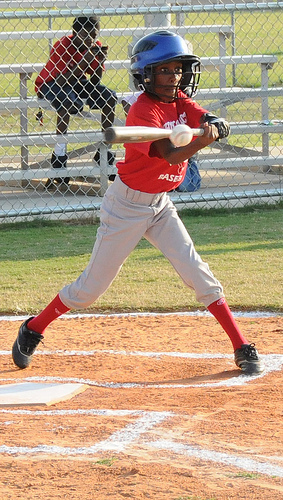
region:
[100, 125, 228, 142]
he is hitting the ball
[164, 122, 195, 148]
the ball is white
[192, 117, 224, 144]
he is holding the bat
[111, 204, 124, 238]
the pants are gray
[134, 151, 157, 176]
the shirt is red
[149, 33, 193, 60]
the helmet is blue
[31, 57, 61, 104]
the boy is sitting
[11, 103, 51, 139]
the fence is gray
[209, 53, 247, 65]
the blechers are metal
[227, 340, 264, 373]
the shoes are black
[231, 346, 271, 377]
Black cleat on top of clay.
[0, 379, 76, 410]
Baseball home plate in the dirt.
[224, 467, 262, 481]
Small patch of dirt in the grass.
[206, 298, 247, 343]
Red socks on athlete's leg.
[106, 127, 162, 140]
Bronze baseball bat in man's hand.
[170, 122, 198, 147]
Baseball being hit by boy.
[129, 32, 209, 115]
Blue helmet on top of boys head.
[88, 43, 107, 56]
Small game in other boy's hand.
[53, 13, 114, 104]
Boy sitting down on bleachers.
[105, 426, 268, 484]
White stripe in the dirt.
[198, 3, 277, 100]
Tall chain link fence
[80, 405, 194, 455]
Chalk lines on baseball field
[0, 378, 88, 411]
Home plate of baseball diamond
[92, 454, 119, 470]
Small patch of grass growing on baseball field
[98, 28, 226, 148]
Boy hitting a baseball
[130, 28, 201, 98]
Boy wearing blue helmet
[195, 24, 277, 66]
Bleachers at baseball field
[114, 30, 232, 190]
Boy wearing red shirt with white writing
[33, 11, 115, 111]
Boy sitting on bleachers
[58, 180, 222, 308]
Gray baseball pants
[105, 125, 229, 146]
A baseball bat striking a baseball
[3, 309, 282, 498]
White lines on the baseball field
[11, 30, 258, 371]
A baseball player swinging the bat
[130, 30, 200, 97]
A helmet with a face guard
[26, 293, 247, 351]
Red ankle high socks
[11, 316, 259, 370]
Black and white cleats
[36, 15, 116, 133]
A spectator in the stands looking at their phone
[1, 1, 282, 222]
A metal chain link fence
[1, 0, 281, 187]
Metal stands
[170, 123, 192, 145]
A baseball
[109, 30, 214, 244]
boy hit the ball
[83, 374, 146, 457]
white lines on the ground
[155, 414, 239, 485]
white lines on the ground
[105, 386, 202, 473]
white lines on the ground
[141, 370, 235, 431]
white lines on the ground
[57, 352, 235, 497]
white lines on the ground